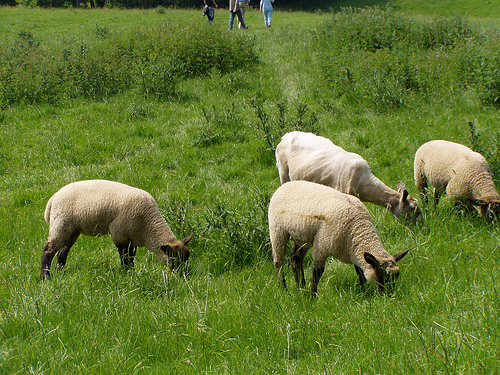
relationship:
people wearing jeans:
[201, 0, 274, 30] [260, 10, 274, 26]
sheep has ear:
[275, 131, 425, 227] [400, 191, 410, 202]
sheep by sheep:
[275, 131, 425, 227] [266, 182, 410, 304]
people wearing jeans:
[201, 0, 274, 30] [228, 13, 247, 31]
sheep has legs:
[266, 182, 410, 304] [273, 245, 366, 291]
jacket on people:
[200, 6, 217, 19] [201, 0, 274, 30]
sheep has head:
[266, 182, 410, 304] [363, 249, 411, 295]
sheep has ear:
[266, 182, 410, 304] [364, 253, 382, 269]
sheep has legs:
[40, 177, 195, 281] [41, 240, 137, 280]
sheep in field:
[266, 182, 410, 304] [2, 7, 500, 373]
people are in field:
[201, 2, 274, 29] [2, 7, 500, 373]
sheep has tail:
[40, 177, 195, 281] [44, 195, 52, 223]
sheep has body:
[266, 182, 410, 304] [268, 184, 364, 261]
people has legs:
[201, 0, 274, 30] [230, 12, 247, 29]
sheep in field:
[275, 131, 425, 227] [2, 7, 500, 373]